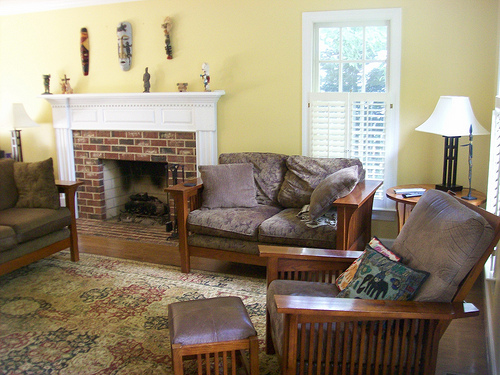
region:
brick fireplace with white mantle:
[0, 92, 243, 237]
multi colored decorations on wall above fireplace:
[63, 12, 195, 72]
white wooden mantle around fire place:
[42, 90, 232, 162]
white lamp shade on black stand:
[416, 87, 482, 204]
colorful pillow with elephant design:
[346, 242, 425, 314]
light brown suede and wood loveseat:
[172, 137, 396, 246]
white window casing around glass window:
[296, 9, 426, 232]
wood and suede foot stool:
[158, 284, 266, 372]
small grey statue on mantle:
[141, 69, 155, 102]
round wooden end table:
[383, 175, 498, 217]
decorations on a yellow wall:
[68, 13, 191, 74]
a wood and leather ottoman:
[158, 293, 260, 373]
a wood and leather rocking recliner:
[266, 213, 487, 357]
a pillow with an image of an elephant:
[344, 237, 412, 308]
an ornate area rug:
[26, 268, 166, 370]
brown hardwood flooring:
[116, 239, 168, 264]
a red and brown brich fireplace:
[75, 125, 194, 226]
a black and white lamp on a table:
[422, 102, 492, 195]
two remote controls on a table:
[388, 184, 425, 202]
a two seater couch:
[173, 135, 390, 272]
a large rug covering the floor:
[2, 220, 174, 373]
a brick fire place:
[63, 84, 228, 189]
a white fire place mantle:
[14, 85, 228, 154]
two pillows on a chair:
[315, 229, 432, 309]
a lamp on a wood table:
[404, 85, 485, 207]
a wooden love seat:
[159, 167, 381, 257]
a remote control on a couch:
[179, 172, 200, 195]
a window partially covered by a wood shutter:
[304, 26, 398, 151]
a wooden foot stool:
[162, 279, 256, 371]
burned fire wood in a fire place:
[114, 167, 174, 227]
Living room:
[6, 14, 487, 374]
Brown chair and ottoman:
[157, 177, 497, 367]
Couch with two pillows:
[166, 131, 383, 276]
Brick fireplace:
[67, 120, 198, 256]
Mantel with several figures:
[33, 58, 231, 124]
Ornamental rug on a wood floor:
[77, 237, 166, 371]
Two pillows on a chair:
[319, 220, 469, 315]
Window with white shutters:
[285, 7, 408, 153]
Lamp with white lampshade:
[406, 80, 491, 205]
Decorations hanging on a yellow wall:
[61, 15, 205, 80]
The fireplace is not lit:
[47, 87, 232, 247]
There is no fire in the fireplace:
[66, 134, 191, 231]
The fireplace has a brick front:
[41, 105, 211, 252]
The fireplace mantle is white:
[31, 85, 227, 238]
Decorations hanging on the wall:
[69, 17, 206, 77]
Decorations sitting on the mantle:
[37, 65, 232, 104]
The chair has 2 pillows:
[331, 182, 479, 351]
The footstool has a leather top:
[128, 278, 273, 372]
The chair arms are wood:
[255, 195, 485, 367]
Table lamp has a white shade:
[373, 63, 489, 230]